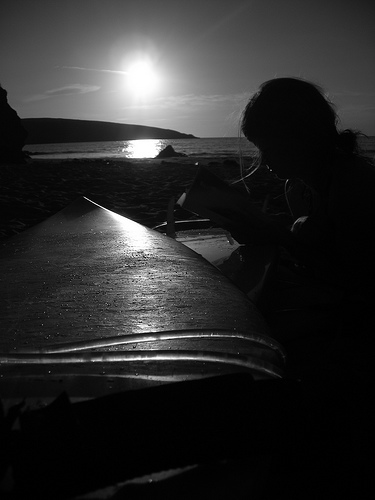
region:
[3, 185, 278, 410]
The surfboard is wet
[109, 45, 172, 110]
The sun is in the sky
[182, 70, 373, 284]
The woman is reading a book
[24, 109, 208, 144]
A mountain is beside the water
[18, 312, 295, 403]
Curved design on the surfboard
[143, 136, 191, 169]
There is a pile of sand by the water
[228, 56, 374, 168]
The woman has long hair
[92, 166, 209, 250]
Sand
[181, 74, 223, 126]
Thin clouds in the sky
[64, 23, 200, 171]
The sun is about to set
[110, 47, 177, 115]
Sun shining very bright.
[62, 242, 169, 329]
Sand on the board.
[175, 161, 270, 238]
A book in her hand.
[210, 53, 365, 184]
A girl with long hair.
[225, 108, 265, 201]
Her hair hangs down.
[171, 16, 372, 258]
A girl reads a book.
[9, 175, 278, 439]
A surf board on the ground.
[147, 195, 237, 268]
Another surf board.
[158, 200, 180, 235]
Fin of the board.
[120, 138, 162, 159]
Reflection in the water.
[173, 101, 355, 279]
girl reading a book on beach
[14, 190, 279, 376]
surfboard on the beach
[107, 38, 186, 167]
sun shining on the beach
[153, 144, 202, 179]
pile of sand on the beach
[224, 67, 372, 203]
girls with hair blowing in the wind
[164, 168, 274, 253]
book on the beach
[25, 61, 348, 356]
girl sitting with her surfboard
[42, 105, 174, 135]
mountain across the water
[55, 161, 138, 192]
sand beach with footprints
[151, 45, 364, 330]
girl enjoying the sun on the beach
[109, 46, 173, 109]
sun in sky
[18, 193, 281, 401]
boat on beach near water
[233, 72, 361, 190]
head of woman near boat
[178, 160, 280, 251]
book being read by woman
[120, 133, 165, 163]
reflection of sun on water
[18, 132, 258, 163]
water in a bay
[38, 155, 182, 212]
rocky beach near water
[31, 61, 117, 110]
clouds in sky near sun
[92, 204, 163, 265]
sun reflecting off boat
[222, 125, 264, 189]
strand of hair from girl reading book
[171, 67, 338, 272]
Woman reading a book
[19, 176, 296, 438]
Surfboard on a beach a sunset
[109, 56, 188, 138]
Sun rising over the water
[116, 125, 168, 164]
Sun reflected on the water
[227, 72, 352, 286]
Woman sitting on a beach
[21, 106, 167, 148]
Hill in the background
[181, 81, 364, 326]
Woman holding a book on the beach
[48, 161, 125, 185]
Sand on a beach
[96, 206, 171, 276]
Sun reflected off a surfboard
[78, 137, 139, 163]
Water under a morning sun